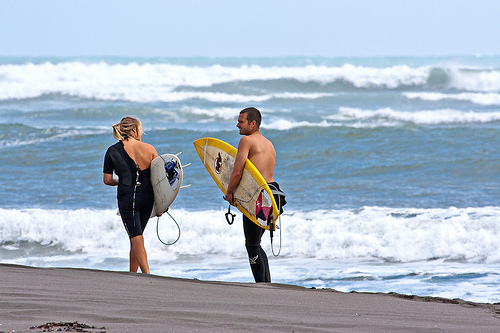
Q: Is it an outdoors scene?
A: Yes, it is outdoors.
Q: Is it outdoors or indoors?
A: It is outdoors.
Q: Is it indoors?
A: No, it is outdoors.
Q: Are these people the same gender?
A: No, they are both male and female.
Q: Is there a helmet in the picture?
A: No, there are no helmets.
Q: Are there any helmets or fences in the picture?
A: No, there are no helmets or fences.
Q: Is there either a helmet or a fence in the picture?
A: No, there are no helmets or fences.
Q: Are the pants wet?
A: Yes, the pants are wet.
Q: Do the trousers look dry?
A: No, the trousers are wet.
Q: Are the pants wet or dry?
A: The pants are wet.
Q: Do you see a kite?
A: No, there are no kites.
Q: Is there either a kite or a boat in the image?
A: No, there are no kites or boats.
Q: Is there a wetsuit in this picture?
A: Yes, there is a wetsuit.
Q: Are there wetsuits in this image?
A: Yes, there is a wetsuit.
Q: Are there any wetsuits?
A: Yes, there is a wetsuit.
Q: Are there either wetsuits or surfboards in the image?
A: Yes, there is a wetsuit.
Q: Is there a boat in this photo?
A: No, there are no boats.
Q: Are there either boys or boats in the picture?
A: No, there are no boats or boys.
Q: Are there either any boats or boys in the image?
A: No, there are no boats or boys.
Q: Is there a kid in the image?
A: No, there are no children.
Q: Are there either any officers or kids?
A: No, there are no kids or officers.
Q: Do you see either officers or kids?
A: No, there are no kids or officers.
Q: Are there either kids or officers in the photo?
A: No, there are no kids or officers.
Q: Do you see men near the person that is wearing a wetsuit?
A: Yes, there is a man near the woman.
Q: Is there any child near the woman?
A: No, there is a man near the woman.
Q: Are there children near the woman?
A: No, there is a man near the woman.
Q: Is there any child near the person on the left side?
A: No, there is a man near the woman.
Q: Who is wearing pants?
A: The man is wearing pants.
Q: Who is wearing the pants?
A: The man is wearing pants.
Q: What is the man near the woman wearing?
A: The man is wearing trousers.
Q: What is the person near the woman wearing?
A: The man is wearing trousers.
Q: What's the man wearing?
A: The man is wearing trousers.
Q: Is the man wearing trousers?
A: Yes, the man is wearing trousers.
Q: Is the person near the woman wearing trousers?
A: Yes, the man is wearing trousers.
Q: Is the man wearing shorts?
A: No, the man is wearing trousers.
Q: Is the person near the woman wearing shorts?
A: No, the man is wearing trousers.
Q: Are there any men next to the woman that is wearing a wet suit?
A: Yes, there is a man next to the woman.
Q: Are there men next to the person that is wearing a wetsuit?
A: Yes, there is a man next to the woman.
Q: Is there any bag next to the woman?
A: No, there is a man next to the woman.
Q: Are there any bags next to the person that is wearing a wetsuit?
A: No, there is a man next to the woman.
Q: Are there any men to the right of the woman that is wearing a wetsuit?
A: Yes, there is a man to the right of the woman.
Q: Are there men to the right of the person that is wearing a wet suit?
A: Yes, there is a man to the right of the woman.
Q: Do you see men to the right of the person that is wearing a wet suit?
A: Yes, there is a man to the right of the woman.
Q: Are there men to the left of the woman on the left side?
A: No, the man is to the right of the woman.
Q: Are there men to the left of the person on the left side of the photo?
A: No, the man is to the right of the woman.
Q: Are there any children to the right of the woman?
A: No, there is a man to the right of the woman.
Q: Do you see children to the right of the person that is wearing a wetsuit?
A: No, there is a man to the right of the woman.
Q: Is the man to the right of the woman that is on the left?
A: Yes, the man is to the right of the woman.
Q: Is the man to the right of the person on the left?
A: Yes, the man is to the right of the woman.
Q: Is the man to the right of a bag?
A: No, the man is to the right of the woman.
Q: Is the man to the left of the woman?
A: No, the man is to the right of the woman.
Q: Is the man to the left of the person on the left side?
A: No, the man is to the right of the woman.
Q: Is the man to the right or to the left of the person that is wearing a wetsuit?
A: The man is to the right of the woman.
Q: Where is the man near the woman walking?
A: The man is walking on the beach.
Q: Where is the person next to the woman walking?
A: The man is walking on the beach.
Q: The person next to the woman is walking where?
A: The man is walking on the beach.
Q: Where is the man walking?
A: The man is walking on the beach.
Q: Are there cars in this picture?
A: No, there are no cars.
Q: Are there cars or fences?
A: No, there are no cars or fences.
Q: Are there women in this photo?
A: Yes, there is a woman.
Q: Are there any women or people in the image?
A: Yes, there is a woman.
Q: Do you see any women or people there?
A: Yes, there is a woman.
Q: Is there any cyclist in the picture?
A: No, there are no cyclists.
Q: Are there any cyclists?
A: No, there are no cyclists.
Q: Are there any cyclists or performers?
A: No, there are no cyclists or performers.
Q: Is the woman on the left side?
A: Yes, the woman is on the left of the image.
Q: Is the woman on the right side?
A: No, the woman is on the left of the image.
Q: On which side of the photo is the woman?
A: The woman is on the left of the image.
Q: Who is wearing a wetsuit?
A: The woman is wearing a wetsuit.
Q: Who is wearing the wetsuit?
A: The woman is wearing a wetsuit.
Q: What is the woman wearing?
A: The woman is wearing a wetsuit.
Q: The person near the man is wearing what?
A: The woman is wearing a wetsuit.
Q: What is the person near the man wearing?
A: The woman is wearing a wetsuit.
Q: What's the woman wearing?
A: The woman is wearing a wetsuit.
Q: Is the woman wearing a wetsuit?
A: Yes, the woman is wearing a wetsuit.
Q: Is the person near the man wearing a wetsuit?
A: Yes, the woman is wearing a wetsuit.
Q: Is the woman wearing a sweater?
A: No, the woman is wearing a wetsuit.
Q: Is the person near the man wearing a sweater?
A: No, the woman is wearing a wetsuit.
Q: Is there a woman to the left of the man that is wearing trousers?
A: Yes, there is a woman to the left of the man.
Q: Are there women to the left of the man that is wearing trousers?
A: Yes, there is a woman to the left of the man.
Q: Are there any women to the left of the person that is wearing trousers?
A: Yes, there is a woman to the left of the man.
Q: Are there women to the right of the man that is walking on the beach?
A: No, the woman is to the left of the man.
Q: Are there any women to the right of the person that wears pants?
A: No, the woman is to the left of the man.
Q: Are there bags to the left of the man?
A: No, there is a woman to the left of the man.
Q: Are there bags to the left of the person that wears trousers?
A: No, there is a woman to the left of the man.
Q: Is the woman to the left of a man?
A: Yes, the woman is to the left of a man.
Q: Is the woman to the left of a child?
A: No, the woman is to the left of a man.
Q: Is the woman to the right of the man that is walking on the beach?
A: No, the woman is to the left of the man.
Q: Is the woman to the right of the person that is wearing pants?
A: No, the woman is to the left of the man.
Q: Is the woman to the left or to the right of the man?
A: The woman is to the left of the man.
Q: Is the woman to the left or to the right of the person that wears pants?
A: The woman is to the left of the man.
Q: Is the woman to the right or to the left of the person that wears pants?
A: The woman is to the left of the man.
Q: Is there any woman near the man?
A: Yes, there is a woman near the man.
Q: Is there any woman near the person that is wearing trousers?
A: Yes, there is a woman near the man.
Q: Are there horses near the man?
A: No, there is a woman near the man.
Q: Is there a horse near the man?
A: No, there is a woman near the man.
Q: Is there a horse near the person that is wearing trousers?
A: No, there is a woman near the man.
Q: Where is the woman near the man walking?
A: The woman is walking on the beach.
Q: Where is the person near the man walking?
A: The woman is walking on the beach.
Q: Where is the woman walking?
A: The woman is walking on the beach.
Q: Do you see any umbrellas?
A: No, there are no umbrellas.